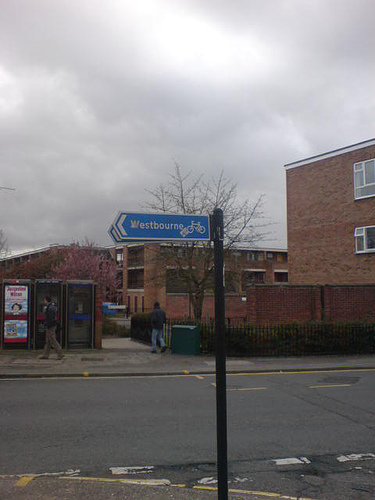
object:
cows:
[3, 380, 372, 480]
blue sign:
[106, 209, 211, 244]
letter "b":
[154, 220, 159, 230]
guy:
[149, 300, 167, 354]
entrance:
[102, 287, 150, 350]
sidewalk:
[0, 333, 374, 376]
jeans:
[152, 327, 166, 351]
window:
[266, 252, 274, 258]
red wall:
[164, 291, 373, 327]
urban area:
[1, 134, 374, 371]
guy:
[39, 291, 68, 363]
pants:
[41, 321, 63, 357]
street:
[0, 353, 374, 500]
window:
[352, 158, 373, 200]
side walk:
[162, 371, 206, 441]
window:
[353, 223, 375, 256]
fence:
[160, 315, 374, 357]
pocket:
[45, 303, 57, 327]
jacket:
[149, 307, 166, 328]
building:
[286, 140, 375, 283]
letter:
[130, 221, 186, 230]